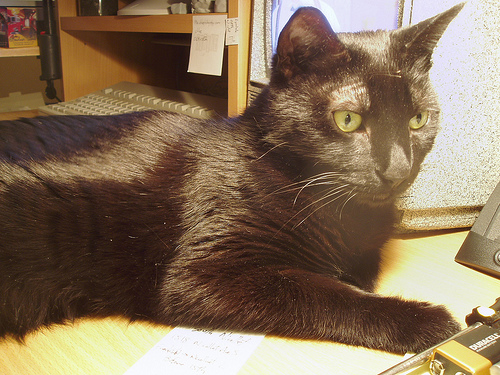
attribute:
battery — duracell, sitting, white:
[421, 316, 495, 374]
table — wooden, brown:
[395, 250, 456, 293]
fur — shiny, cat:
[56, 119, 184, 207]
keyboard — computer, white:
[80, 74, 175, 115]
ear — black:
[261, 3, 346, 87]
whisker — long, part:
[251, 160, 363, 261]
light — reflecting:
[447, 64, 497, 132]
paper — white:
[188, 13, 227, 82]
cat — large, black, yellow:
[70, 12, 451, 336]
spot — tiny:
[176, 157, 278, 220]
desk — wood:
[62, 320, 159, 358]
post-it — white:
[177, 18, 246, 86]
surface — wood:
[44, 337, 79, 354]